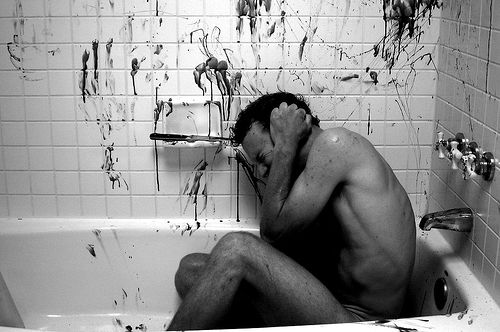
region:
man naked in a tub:
[125, 62, 365, 328]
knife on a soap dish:
[134, 106, 259, 172]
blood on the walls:
[73, 24, 268, 168]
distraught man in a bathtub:
[150, 57, 415, 327]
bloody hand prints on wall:
[54, 19, 148, 177]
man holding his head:
[208, 78, 320, 210]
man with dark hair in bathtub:
[202, 104, 362, 234]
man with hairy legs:
[149, 210, 265, 330]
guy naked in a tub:
[132, 63, 471, 329]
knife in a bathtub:
[92, 64, 337, 267]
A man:
[231, 76, 379, 307]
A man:
[253, 127, 335, 313]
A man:
[221, 164, 316, 321]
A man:
[234, 213, 279, 313]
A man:
[288, 128, 364, 328]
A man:
[274, 148, 328, 288]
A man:
[279, 227, 316, 315]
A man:
[307, 179, 350, 316]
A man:
[280, 182, 316, 293]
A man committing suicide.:
[169, 87, 423, 329]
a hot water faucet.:
[424, 116, 469, 171]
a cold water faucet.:
[459, 142, 494, 187]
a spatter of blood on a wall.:
[79, 45, 90, 114]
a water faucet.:
[411, 208, 477, 240]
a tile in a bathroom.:
[50, 139, 84, 176]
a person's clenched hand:
[260, 99, 322, 148]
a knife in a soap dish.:
[147, 90, 254, 196]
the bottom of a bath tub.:
[91, 290, 163, 328]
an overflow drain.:
[423, 254, 460, 314]